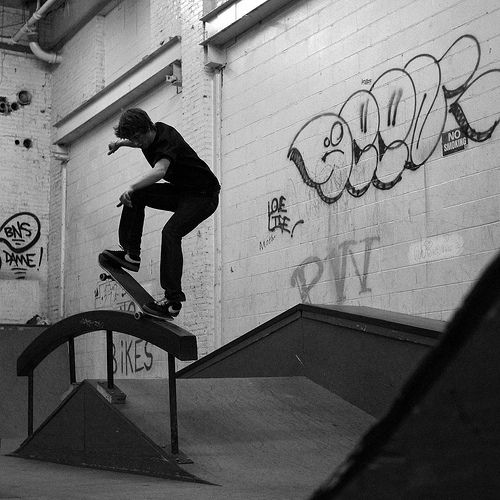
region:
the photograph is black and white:
[3, 2, 499, 495]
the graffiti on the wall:
[286, 22, 493, 204]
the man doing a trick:
[91, 107, 220, 327]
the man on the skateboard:
[98, 97, 241, 341]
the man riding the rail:
[5, 85, 239, 463]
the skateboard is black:
[84, 243, 179, 327]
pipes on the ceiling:
[1, 1, 80, 68]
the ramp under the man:
[11, 359, 379, 486]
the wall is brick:
[223, 42, 498, 271]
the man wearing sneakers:
[88, 242, 200, 324]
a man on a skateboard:
[96, 108, 222, 315]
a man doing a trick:
[94, 105, 229, 336]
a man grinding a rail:
[16, 100, 228, 472]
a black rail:
[14, 308, 201, 476]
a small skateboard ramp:
[8, 362, 383, 490]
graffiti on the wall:
[259, 65, 499, 304]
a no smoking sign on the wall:
[439, 126, 470, 154]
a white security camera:
[162, 67, 181, 91]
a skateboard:
[97, 246, 174, 324]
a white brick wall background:
[0, 0, 497, 380]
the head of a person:
[111, 105, 158, 151]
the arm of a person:
[127, 133, 178, 189]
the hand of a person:
[113, 185, 139, 211]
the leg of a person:
[156, 204, 215, 295]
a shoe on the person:
[141, 287, 190, 320]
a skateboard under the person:
[93, 247, 177, 327]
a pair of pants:
[117, 175, 224, 305]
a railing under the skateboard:
[10, 304, 203, 383]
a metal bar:
[163, 348, 185, 456]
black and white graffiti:
[288, 102, 464, 229]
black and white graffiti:
[311, 114, 417, 201]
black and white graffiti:
[282, 103, 378, 225]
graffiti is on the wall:
[244, 39, 493, 194]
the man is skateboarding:
[23, 62, 234, 348]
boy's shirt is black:
[134, 137, 237, 220]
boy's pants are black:
[100, 175, 234, 284]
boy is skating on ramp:
[41, 84, 248, 322]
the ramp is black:
[9, 302, 236, 413]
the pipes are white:
[1, 2, 116, 92]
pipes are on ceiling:
[0, 0, 100, 79]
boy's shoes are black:
[106, 240, 231, 352]